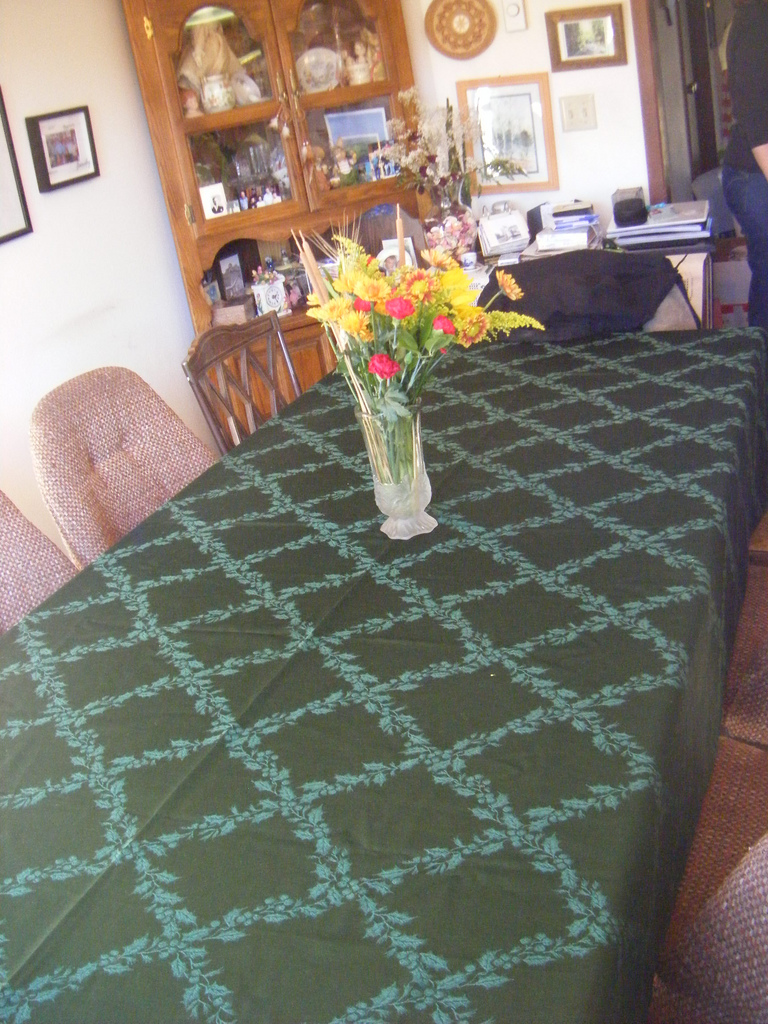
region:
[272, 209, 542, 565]
a vase of colorful flowers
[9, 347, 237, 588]
a chair made of fabric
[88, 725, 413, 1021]
leaf design on green table cloth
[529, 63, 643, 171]
light switch located on the wall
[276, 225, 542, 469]
pink and yellow flowers in the vase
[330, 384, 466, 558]
a flower vase in the center of the table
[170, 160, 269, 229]
a vintage photo on the china cabinet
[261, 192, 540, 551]
Flowers in a vase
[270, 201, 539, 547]
Flowers are in a vase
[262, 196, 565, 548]
Flowers in a glass vase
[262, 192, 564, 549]
Flowers are in a glass vase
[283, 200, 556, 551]
Yellow and pink flowers in a vase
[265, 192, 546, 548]
Yellow and pink flowers are in a vase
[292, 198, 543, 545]
Yellow and pink flowers in a glass vase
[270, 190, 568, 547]
Yellow and pink flowers are in a glass vase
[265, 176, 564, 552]
Flowers are in the center of the table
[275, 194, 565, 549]
Yellow and pink flowers are in the center of the table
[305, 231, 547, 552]
Vase with flowers on the table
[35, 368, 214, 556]
Chair sitting under a table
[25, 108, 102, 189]
Picture on the wall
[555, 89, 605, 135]
Light switch on the wall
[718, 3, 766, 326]
Lady standing with back turned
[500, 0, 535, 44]
Thermostat on the wall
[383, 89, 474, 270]
Vase of Purple and white flowers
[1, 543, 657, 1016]
A green and blue tablecloth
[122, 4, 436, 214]
Light brown china cabinet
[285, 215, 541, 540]
yellow flowers in vase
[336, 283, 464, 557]
pink flowers in clear vase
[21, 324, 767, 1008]
black tablecloth with blue leaf motif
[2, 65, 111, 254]
pictures with black frames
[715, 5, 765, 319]
person wearing black shirt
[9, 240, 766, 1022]
chairs around the table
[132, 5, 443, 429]
cabinet in the corner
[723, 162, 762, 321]
blue jeans person is wearing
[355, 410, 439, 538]
clear glass vase on the table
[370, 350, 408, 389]
Pink flower inside of clear vase.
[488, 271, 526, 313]
Yellow flower in vase.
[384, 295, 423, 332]
Pink flower in vase.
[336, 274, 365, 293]
Yellow flower in vase.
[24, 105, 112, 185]
Black frame hanging on wall.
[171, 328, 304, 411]
Wood brown chair up to table.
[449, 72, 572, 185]
Brown frame hanging on wall.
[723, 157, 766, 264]
Person wearing blue jeans.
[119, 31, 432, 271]
Wood hutch in corner.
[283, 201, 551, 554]
a vase containing flowers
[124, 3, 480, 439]
a corner cabinet with glass doors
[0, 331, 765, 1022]
table cloth covering a table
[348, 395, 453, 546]
clear glass vase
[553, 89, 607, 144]
light switches on the wall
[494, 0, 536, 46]
white thermostate on the wall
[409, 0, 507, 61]
a round object hanging on the wall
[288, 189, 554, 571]
flowers in a vase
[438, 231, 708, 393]
a coat on a chair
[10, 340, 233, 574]
a brown cloth chair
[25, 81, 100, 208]
a picture on the wall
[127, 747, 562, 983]
blue flowers on a table cloth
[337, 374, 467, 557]
a glass flower vase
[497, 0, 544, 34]
a white box on wall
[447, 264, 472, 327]
a yellow flower in vase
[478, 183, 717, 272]
a very messy desk